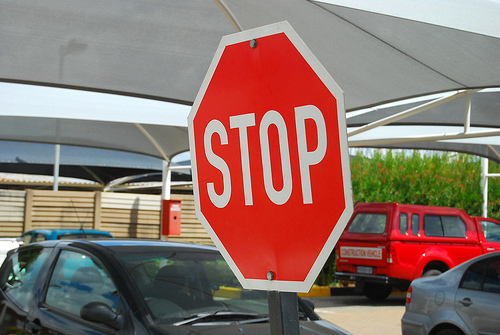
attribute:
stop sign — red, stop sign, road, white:
[187, 20, 355, 292]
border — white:
[185, 21, 353, 294]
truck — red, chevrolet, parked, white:
[334, 201, 499, 301]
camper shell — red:
[337, 200, 478, 244]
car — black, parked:
[0, 240, 354, 333]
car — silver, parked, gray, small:
[398, 247, 498, 334]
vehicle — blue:
[15, 226, 112, 243]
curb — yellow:
[213, 284, 330, 298]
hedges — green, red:
[342, 149, 499, 216]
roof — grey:
[1, 0, 499, 160]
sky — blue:
[321, 0, 497, 162]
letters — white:
[202, 104, 329, 210]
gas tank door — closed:
[433, 287, 447, 307]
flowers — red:
[376, 160, 468, 194]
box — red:
[161, 194, 183, 239]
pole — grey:
[160, 158, 173, 241]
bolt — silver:
[247, 38, 257, 49]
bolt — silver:
[265, 268, 276, 283]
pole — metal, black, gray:
[265, 290, 302, 334]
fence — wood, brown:
[0, 188, 218, 249]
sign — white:
[338, 245, 383, 261]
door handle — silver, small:
[457, 298, 473, 307]